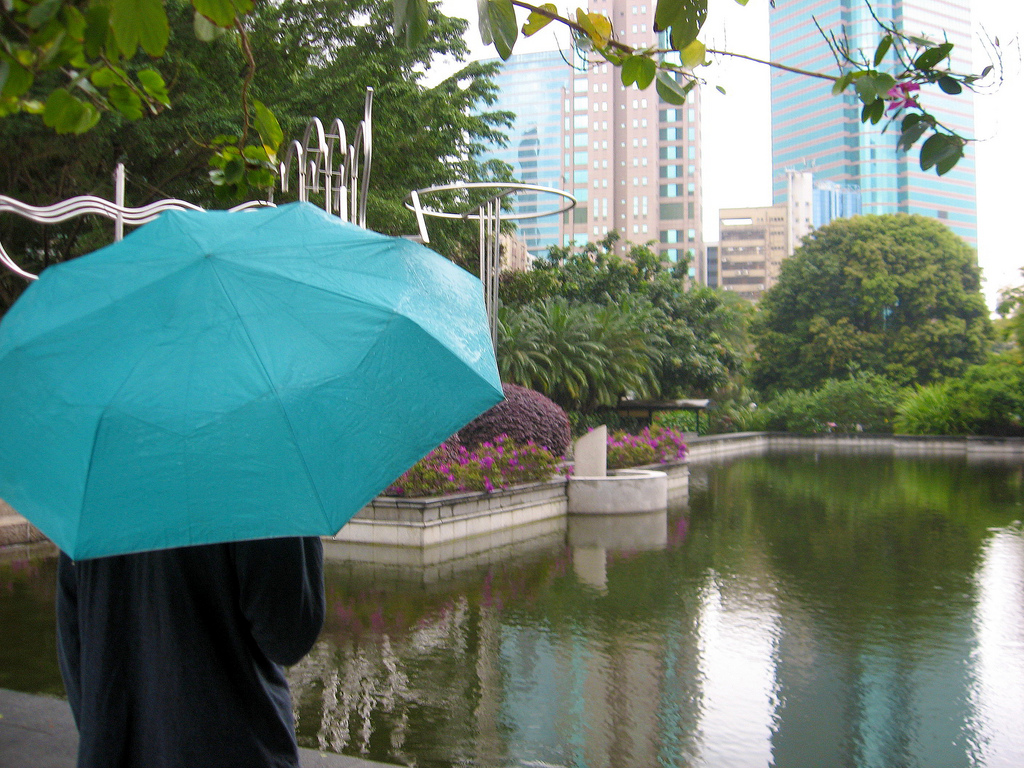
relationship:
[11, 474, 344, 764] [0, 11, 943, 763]
people enjoying outdoors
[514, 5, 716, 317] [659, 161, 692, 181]
building has window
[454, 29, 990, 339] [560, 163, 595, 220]
building has a window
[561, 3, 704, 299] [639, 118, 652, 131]
building has window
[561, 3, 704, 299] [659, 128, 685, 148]
building has window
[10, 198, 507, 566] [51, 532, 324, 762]
umbrella held by person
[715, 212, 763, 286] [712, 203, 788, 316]
windows on side of building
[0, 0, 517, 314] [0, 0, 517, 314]
tree on tree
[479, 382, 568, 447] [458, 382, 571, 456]
flowers on flowers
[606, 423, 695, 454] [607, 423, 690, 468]
flowers on flowers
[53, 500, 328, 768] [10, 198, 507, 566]
people holding umbrella